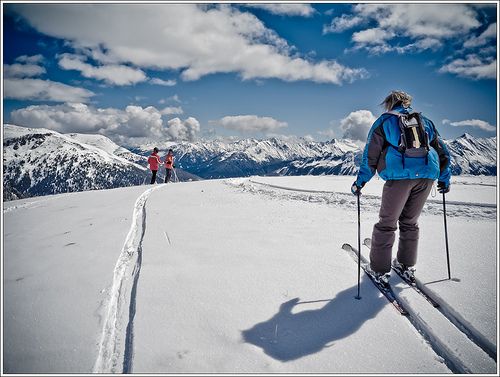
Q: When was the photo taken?
A: In the wintertime.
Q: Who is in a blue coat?
A: A skier.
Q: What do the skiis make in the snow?
A: Tracks.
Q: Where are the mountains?
A: In the distance.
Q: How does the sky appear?
A: Cloudy.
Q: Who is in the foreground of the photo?
A: A man on skis.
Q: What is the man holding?
A: Ski poles.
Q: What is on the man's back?
A: A small backpack.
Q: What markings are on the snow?
A: Ski tracks.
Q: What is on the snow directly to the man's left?
A: The man's shadow.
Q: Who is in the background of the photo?
A: Two skiers in bright jackets.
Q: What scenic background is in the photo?
A: Snow covered mountains.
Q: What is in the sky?
A: Clouds.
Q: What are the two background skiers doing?
A: Waiting for the foreground skier to catch up.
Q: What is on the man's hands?
A: Ski gloves.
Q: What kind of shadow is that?
A: A person's shadow.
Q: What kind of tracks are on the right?
A: The tracks from ski poles.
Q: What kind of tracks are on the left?
A: Tracks from skis.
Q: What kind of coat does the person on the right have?
A: A blue coat.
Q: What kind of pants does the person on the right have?
A: Grey pants.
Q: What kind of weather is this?
A: Clear with a few clouds.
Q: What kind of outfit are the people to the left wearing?
A: Red coats and black pants.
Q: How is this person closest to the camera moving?
A: On skies.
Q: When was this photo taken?
A: During the daytime.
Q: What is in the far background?
A: Mountains.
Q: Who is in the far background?
A: Two people.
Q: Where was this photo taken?
A: On a ski slope.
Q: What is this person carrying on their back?
A: A backpack.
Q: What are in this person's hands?
A: Ski poles.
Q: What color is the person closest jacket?
A: Blue.